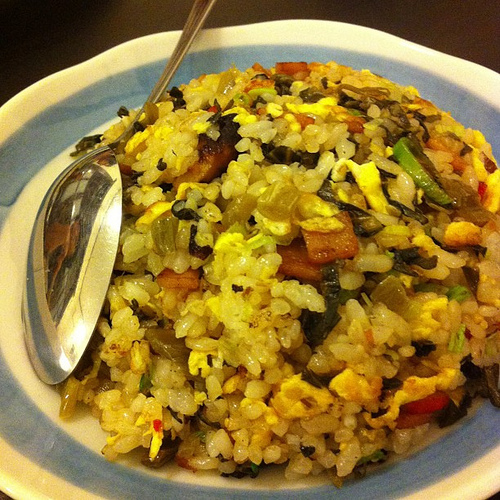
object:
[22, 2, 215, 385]
spoon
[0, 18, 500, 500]
bowl.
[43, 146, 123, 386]
reflection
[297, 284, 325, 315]
rice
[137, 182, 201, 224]
cheese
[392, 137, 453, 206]
peppers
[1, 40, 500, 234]
stripe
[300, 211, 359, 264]
brown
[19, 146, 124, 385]
large.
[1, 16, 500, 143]
white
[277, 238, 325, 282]
may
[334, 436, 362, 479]
grains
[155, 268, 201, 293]
ingredients.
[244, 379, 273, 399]
tiny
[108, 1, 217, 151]
handle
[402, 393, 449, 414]
bit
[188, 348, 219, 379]
piece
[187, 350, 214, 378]
egg.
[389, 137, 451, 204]
prieces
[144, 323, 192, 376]
piece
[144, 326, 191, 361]
onion.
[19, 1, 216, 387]
shiny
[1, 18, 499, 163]
wavey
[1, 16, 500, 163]
rim.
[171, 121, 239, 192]
meal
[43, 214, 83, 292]
person.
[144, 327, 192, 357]
chopped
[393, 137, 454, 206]
chopped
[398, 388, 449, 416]
chopped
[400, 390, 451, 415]
pepper.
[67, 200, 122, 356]
light.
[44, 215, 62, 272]
phone.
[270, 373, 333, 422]
egg